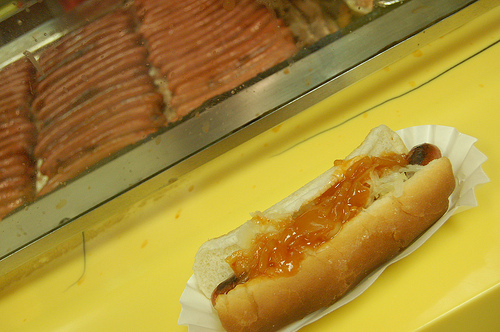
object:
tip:
[401, 141, 450, 171]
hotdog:
[38, 103, 161, 177]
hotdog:
[34, 64, 150, 131]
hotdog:
[31, 30, 143, 97]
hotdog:
[31, 21, 133, 81]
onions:
[380, 170, 397, 173]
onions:
[376, 181, 392, 187]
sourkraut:
[290, 188, 356, 232]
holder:
[176, 121, 494, 332]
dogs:
[171, 43, 301, 117]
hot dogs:
[34, 117, 169, 200]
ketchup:
[231, 207, 338, 271]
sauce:
[267, 227, 307, 248]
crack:
[68, 228, 88, 289]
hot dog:
[0, 0, 305, 222]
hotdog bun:
[186, 122, 461, 332]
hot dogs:
[31, 62, 152, 131]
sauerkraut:
[254, 194, 362, 261]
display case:
[0, 0, 475, 261]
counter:
[0, 0, 500, 332]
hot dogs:
[167, 36, 300, 121]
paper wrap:
[453, 127, 488, 209]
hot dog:
[206, 138, 448, 310]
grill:
[0, 0, 469, 265]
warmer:
[0, 0, 477, 260]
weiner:
[208, 141, 444, 308]